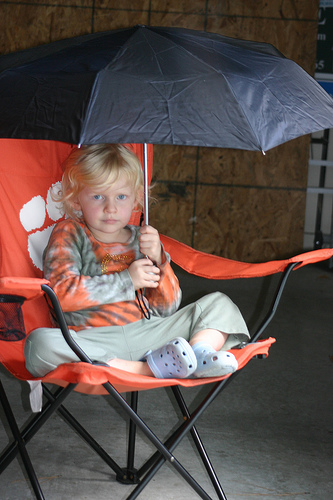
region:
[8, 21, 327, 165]
Opened black umbrella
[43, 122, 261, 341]
Small child holding an umbrella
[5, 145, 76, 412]
Orange, white and black chair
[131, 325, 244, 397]
Small grey croc shoes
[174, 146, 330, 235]
Piece of plywood against wall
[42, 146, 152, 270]
Small child with wavy blonde hair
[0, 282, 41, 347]
Black mesh cup holder on chair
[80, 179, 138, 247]
Small child with blue eyes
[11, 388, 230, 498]
Black metal chair legs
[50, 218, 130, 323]
Orange and grey shirt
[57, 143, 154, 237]
young child with blond hair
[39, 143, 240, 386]
young child sitting in chair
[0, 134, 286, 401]
orange foldup camp chair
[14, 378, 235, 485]
black metal frame of camp chair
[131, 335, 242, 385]
light plastic clog shoes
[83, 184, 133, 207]
child's light blue eyes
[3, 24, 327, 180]
black collapsible umbrella held open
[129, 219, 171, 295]
child's hands holding umbrella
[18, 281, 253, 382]
light green toddler pants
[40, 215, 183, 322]
green and orange long sleeve child's shirt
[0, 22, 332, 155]
a black umbrella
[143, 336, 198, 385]
a white shoe on the child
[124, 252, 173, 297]
a hand of the child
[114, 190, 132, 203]
the eye of a boy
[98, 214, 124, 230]
the mouth of a boy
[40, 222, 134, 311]
the arm of a boy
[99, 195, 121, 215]
the nose of a boy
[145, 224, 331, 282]
a red arm rest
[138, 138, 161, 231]
a metal umbrella post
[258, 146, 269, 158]
the tip of an umbrella frame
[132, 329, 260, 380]
the child is wearing white crocs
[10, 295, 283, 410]
child seating in folding chair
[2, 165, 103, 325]
the seat has a paw print on it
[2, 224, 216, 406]
the seat is orange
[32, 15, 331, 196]
the umbrella is black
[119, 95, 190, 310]
the child is holding the umbrella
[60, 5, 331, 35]
the wall has plywood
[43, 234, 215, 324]
the child's shirt is orange and grey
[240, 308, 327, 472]
the floor is cement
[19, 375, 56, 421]
tag on the seat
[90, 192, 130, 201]
Blue eyes of a girl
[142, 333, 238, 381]
Two croc shoes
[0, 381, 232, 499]
Black metal legs of a folding chair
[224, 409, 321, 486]
Concrete of a floor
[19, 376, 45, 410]
White tag hanging from an orange chair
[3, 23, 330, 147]
Open black umbrella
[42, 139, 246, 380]
Girl sitting on an orange chair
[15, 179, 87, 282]
White tiger paw on an orange chair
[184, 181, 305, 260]
Blue lines on plywood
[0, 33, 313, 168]
Plywood wall behind an orange chair